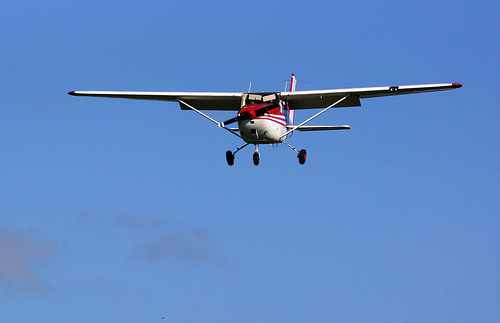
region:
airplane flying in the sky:
[65, 59, 482, 172]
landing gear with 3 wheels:
[225, 143, 320, 170]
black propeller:
[228, 102, 278, 119]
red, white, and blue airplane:
[60, 69, 470, 164]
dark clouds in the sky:
[0, 195, 302, 318]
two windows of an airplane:
[235, 92, 282, 105]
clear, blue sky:
[73, 12, 424, 74]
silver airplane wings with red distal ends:
[64, 75, 459, 115]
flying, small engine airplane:
[60, 65, 465, 165]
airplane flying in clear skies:
[56, 34, 486, 184]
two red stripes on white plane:
[241, 96, 293, 141]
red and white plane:
[228, 87, 302, 152]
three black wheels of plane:
[212, 141, 318, 172]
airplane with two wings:
[55, 60, 477, 177]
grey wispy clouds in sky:
[22, 207, 243, 321]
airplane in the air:
[42, 57, 484, 178]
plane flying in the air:
[38, 45, 488, 191]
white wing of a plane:
[62, 80, 239, 138]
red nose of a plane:
[224, 100, 282, 145]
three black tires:
[220, 142, 310, 169]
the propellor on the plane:
[208, 89, 288, 126]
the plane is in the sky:
[57, 64, 471, 176]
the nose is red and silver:
[221, 93, 297, 156]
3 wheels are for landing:
[213, 137, 318, 174]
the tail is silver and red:
[284, 75, 298, 130]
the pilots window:
[246, 94, 278, 109]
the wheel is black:
[219, 152, 237, 167]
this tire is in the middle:
[250, 151, 265, 165]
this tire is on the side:
[290, 148, 311, 165]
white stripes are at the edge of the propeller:
[216, 118, 231, 133]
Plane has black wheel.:
[283, 146, 339, 196]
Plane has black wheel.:
[247, 144, 282, 182]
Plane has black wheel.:
[222, 143, 243, 168]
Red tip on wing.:
[448, 71, 461, 104]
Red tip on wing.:
[69, 74, 84, 109]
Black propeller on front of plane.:
[217, 100, 285, 140]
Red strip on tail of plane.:
[281, 75, 294, 124]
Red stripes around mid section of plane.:
[251, 95, 294, 134]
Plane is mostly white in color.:
[196, 57, 336, 210]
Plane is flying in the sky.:
[117, 27, 331, 160]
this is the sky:
[19, 115, 156, 197]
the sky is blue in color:
[29, 121, 144, 176]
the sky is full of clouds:
[7, 222, 225, 294]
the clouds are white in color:
[1, 224, 80, 301]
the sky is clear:
[310, 204, 422, 276]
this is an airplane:
[61, 77, 462, 169]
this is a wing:
[65, 85, 242, 110]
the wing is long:
[61, 80, 238, 116]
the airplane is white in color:
[262, 125, 277, 139]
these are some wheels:
[216, 143, 312, 169]